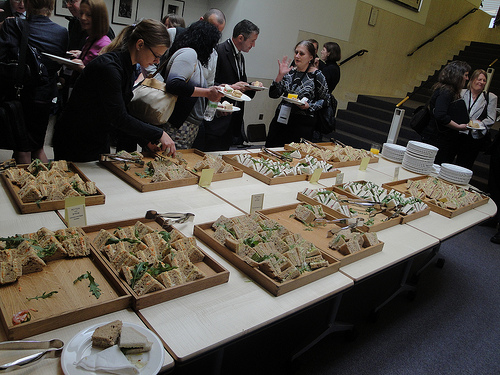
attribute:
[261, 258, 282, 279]
sandwich — triangular, shaped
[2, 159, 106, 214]
box — wooden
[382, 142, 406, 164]
stack — white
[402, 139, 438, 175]
stack — white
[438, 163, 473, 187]
stack — white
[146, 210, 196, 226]
prongs — metal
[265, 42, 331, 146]
woman — talking, mature, standing, older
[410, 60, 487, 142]
woman — standing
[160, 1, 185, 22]
picture — framed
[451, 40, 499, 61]
stair — carpeted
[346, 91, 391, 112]
stair — carpeted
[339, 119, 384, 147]
stair — carpeted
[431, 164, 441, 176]
plates — white, stacked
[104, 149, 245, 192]
boxes — wooden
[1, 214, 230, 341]
boxes — wooden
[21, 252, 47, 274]
shape — triangular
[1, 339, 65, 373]
tong — silver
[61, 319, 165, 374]
plate — white, round, ceramic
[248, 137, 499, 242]
table — white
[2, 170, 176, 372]
table — white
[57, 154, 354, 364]
table — white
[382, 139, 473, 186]
plates — white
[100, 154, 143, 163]
tong — silver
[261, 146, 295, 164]
tong — silver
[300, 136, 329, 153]
tong — silver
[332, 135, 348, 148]
tong — silver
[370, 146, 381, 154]
juice — orange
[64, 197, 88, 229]
card — cardboard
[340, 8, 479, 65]
railing — long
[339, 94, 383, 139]
staircase — grey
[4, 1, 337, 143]
people — eating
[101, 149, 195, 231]
silver — shiny, metal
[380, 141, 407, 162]
plates — stacked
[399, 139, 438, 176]
plates — stacked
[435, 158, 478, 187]
plates — stacked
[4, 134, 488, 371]
table — white